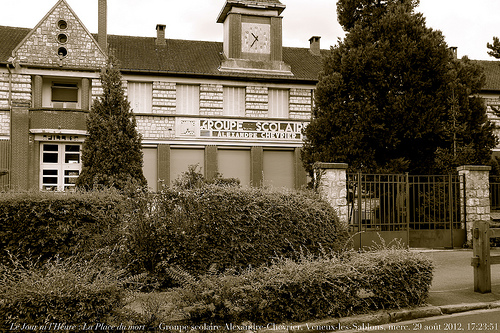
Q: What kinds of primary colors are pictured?
A: Black and white.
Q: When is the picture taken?
A: 10:35.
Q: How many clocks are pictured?
A: One.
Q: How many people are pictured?
A: None.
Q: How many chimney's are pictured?
A: Four.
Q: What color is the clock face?
A: White.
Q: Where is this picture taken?
A: In the city.